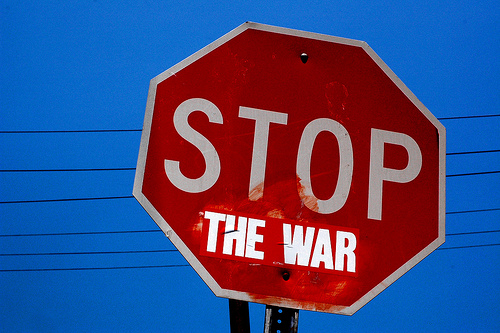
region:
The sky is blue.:
[20, 22, 125, 88]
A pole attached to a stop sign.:
[245, 260, 313, 331]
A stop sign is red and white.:
[121, 7, 462, 315]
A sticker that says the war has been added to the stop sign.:
[195, 195, 370, 285]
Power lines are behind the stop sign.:
[5, 116, 125, 296]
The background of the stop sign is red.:
[245, 61, 332, 94]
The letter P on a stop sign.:
[365, 118, 430, 233]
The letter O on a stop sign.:
[295, 115, 357, 215]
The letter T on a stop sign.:
[230, 95, 290, 208]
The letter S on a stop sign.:
[161, 89, 225, 196]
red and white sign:
[103, 8, 467, 318]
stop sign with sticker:
[95, 14, 487, 319]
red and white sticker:
[172, 198, 377, 280]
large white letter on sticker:
[195, 203, 224, 258]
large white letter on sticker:
[219, 209, 251, 260]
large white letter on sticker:
[237, 213, 270, 268]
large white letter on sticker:
[278, 220, 315, 273]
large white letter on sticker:
[305, 219, 339, 275]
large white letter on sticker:
[329, 226, 361, 282]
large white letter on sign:
[144, 81, 238, 201]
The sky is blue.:
[2, 1, 499, 331]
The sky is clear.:
[2, 1, 499, 330]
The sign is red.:
[123, 15, 450, 321]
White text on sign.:
[160, 89, 430, 226]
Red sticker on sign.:
[195, 204, 364, 281]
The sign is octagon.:
[130, 18, 449, 317]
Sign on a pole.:
[121, 11, 451, 331]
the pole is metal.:
[255, 295, 301, 330]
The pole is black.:
[257, 297, 304, 332]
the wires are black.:
[1, 103, 498, 278]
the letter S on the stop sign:
[158, 85, 224, 196]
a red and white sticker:
[203, 206, 360, 282]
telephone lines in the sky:
[5, 115, 115, 287]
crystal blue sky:
[3, 13, 115, 103]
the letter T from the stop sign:
[227, 89, 291, 206]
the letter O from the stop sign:
[290, 118, 355, 219]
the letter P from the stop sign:
[359, 123, 424, 221]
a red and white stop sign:
[122, 5, 450, 330]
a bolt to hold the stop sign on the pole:
[295, 43, 316, 73]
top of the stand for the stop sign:
[259, 302, 301, 332]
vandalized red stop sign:
[97, 12, 474, 319]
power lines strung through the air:
[30, 104, 105, 291]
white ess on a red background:
[158, 94, 223, 201]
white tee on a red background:
[228, 94, 290, 206]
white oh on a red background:
[291, 108, 361, 222]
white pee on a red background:
[358, 121, 420, 229]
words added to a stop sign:
[198, 204, 372, 275]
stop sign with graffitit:
[108, 2, 468, 323]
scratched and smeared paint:
[194, 167, 344, 277]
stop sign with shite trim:
[102, 11, 466, 316]